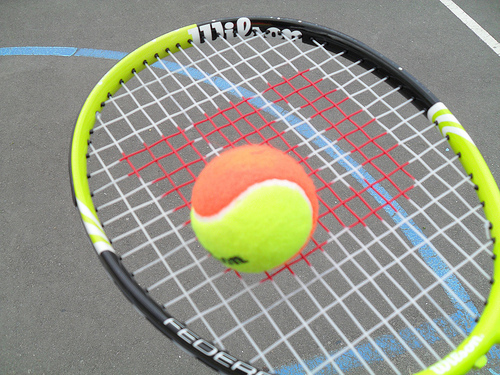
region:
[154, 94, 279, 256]
a ball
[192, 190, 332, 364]
a ball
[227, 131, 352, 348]
a ball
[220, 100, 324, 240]
a ball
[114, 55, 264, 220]
a ball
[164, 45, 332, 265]
a ball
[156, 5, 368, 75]
tennis racquet is made by Wilson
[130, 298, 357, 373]
tennis racquet is endorsed by Roger Federer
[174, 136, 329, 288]
tennis ball is made by Wilson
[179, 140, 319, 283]
tennis ball is orange and yellow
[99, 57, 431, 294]
tennis racquet has a big "W" for Wilson, the manufacturer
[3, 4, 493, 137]
this type of tennis court is called "hard" court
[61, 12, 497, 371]
tennis racquet is yellow and black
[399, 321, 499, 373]
Wilson logo on a tennis racquet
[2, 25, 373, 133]
blue boundary lines on a hard tennis court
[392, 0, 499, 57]
white boundary line on a hard tennis court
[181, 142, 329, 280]
tennis ball on racquet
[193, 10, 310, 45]
wilson logo on side of racquet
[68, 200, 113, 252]
white design on racquet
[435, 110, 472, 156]
edge of tennis racquet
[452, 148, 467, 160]
string hole for racquet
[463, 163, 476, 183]
string hole for racquet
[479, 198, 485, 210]
string hole for racquet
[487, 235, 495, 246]
string hole for racquet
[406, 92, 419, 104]
string hole for racquet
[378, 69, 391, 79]
string hole for racquet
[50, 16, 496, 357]
A tennis racket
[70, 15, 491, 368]
Black and yellow rim on tennis racket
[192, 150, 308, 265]
A yellow and peach colored tennis ball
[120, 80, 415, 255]
White and pink colored net on tennis racket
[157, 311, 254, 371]
Letters on black rim of tennis racket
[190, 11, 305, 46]
Letters saying Wilson on black rim of tennis racket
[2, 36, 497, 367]
Blue lines on cement court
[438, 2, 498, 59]
White line on cement court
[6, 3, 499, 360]
Cement tennis court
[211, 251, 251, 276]
Writing in black on tennis ball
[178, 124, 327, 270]
yellow and orange tennis ball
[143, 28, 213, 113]
white strings on a tennis racket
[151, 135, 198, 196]
red strings on a tennis racket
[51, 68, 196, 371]
yellow and black frame to a tennis racket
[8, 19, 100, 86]
light blue line painted on a tennis court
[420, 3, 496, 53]
white line painted on a tennis court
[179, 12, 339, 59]
brand name printed in white on tennis racket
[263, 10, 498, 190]
black and yellow frame to a tennis racket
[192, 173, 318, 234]
white seam line on tennis ball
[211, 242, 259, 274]
black printed brand name on tennis ball